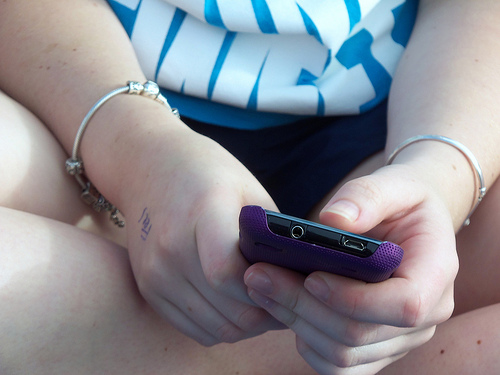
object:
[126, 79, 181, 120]
charms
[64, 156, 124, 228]
charms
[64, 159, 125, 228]
beads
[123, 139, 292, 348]
hand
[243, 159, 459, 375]
hand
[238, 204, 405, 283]
cell phone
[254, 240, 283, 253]
cover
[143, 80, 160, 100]
bead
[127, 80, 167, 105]
beads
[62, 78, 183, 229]
bracelet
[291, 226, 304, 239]
earphone jack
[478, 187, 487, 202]
bead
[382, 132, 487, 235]
bracelet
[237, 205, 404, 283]
purple cover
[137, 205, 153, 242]
tattoo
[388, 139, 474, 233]
wrist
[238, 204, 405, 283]
purple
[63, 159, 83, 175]
bead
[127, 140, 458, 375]
hands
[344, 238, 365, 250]
power input